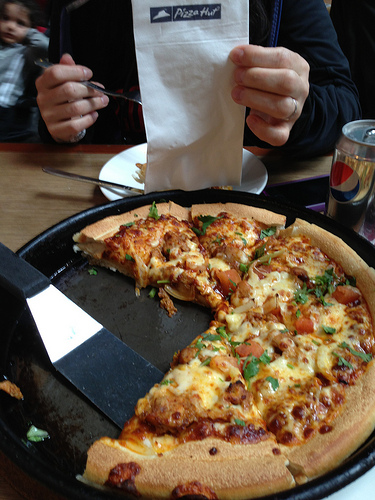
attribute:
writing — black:
[146, 2, 222, 22]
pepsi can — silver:
[326, 116, 372, 233]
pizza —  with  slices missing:
[4, 188, 374, 497]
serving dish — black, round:
[0, 189, 375, 499]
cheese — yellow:
[104, 213, 374, 453]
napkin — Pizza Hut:
[131, 1, 250, 194]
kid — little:
[0, 0, 53, 125]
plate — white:
[102, 135, 276, 210]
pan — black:
[12, 182, 374, 497]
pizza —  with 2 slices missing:
[70, 196, 371, 499]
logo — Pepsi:
[325, 156, 368, 208]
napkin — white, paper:
[138, 28, 230, 157]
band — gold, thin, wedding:
[283, 97, 301, 124]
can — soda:
[324, 115, 373, 247]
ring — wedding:
[288, 99, 298, 120]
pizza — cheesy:
[71, 198, 374, 463]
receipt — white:
[129, 5, 253, 188]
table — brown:
[2, 147, 374, 498]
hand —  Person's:
[33, 51, 110, 140]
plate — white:
[96, 139, 269, 201]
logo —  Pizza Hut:
[151, 9, 168, 20]